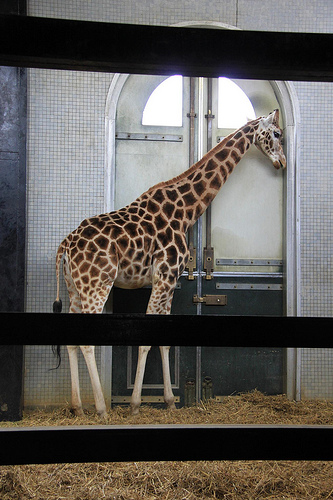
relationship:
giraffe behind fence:
[45, 102, 290, 413] [3, 10, 332, 466]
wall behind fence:
[25, 3, 333, 405] [3, 10, 332, 466]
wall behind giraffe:
[25, 3, 333, 405] [45, 102, 290, 413]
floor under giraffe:
[0, 397, 333, 499] [45, 102, 290, 413]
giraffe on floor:
[45, 102, 290, 413] [0, 397, 333, 499]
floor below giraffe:
[0, 397, 333, 499] [45, 102, 290, 413]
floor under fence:
[0, 397, 333, 499] [3, 10, 332, 466]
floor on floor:
[0, 397, 333, 499] [16, 397, 329, 494]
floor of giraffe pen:
[16, 397, 329, 494] [7, 6, 325, 486]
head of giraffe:
[235, 102, 293, 176] [45, 102, 290, 413]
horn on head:
[270, 107, 282, 125] [235, 102, 293, 176]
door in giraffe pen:
[108, 16, 286, 399] [7, 6, 325, 486]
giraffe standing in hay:
[45, 102, 290, 413] [103, 410, 302, 422]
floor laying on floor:
[0, 397, 333, 499] [0, 397, 333, 499]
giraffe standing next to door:
[45, 102, 290, 413] [108, 16, 286, 399]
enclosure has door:
[12, 18, 326, 495] [108, 16, 286, 399]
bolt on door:
[187, 288, 228, 305] [108, 16, 286, 399]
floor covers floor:
[0, 397, 333, 499] [15, 386, 324, 490]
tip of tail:
[45, 296, 63, 370] [45, 236, 68, 365]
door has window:
[108, 16, 286, 399] [136, 64, 189, 128]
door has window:
[108, 16, 286, 399] [204, 74, 273, 129]